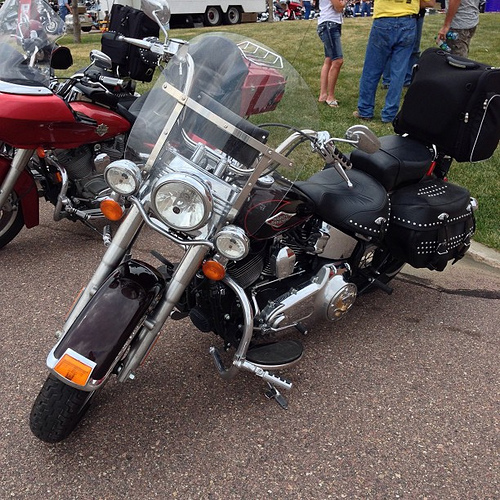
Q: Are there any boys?
A: No, there are no boys.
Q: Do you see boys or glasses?
A: No, there are no boys or glasses.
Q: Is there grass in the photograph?
A: Yes, there is grass.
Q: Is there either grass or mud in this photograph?
A: Yes, there is grass.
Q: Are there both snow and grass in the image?
A: No, there is grass but no snow.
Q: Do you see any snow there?
A: No, there is no snow.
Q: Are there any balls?
A: No, there are no balls.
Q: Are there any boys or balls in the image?
A: No, there are no balls or boys.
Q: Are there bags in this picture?
A: Yes, there is a bag.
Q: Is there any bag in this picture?
A: Yes, there is a bag.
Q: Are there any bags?
A: Yes, there is a bag.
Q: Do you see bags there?
A: Yes, there is a bag.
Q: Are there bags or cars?
A: Yes, there is a bag.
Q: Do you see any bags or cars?
A: Yes, there is a bag.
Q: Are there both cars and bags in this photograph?
A: No, there is a bag but no cars.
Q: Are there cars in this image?
A: No, there are no cars.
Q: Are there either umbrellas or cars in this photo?
A: No, there are no cars or umbrellas.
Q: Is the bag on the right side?
A: Yes, the bag is on the right of the image.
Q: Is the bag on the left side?
A: No, the bag is on the right of the image.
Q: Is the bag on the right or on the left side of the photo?
A: The bag is on the right of the image.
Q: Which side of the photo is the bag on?
A: The bag is on the right of the image.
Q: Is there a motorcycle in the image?
A: Yes, there is a motorcycle.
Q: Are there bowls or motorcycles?
A: Yes, there is a motorcycle.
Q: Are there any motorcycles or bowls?
A: Yes, there is a motorcycle.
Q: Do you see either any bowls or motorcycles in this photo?
A: Yes, there is a motorcycle.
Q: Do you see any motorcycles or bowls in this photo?
A: Yes, there is a motorcycle.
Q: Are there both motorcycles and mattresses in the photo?
A: No, there is a motorcycle but no mattresses.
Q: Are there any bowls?
A: No, there are no bowls.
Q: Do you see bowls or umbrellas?
A: No, there are no bowls or umbrellas.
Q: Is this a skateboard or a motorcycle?
A: This is a motorcycle.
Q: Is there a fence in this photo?
A: No, there are no fences.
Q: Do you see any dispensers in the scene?
A: No, there are no dispensers.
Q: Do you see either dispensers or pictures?
A: No, there are no dispensers or pictures.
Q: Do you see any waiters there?
A: No, there are no waiters.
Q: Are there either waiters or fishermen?
A: No, there are no waiters or fishermen.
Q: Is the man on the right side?
A: Yes, the man is on the right of the image.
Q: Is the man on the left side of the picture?
A: No, the man is on the right of the image.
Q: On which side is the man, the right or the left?
A: The man is on the right of the image.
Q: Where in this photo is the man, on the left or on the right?
A: The man is on the right of the image.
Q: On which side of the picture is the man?
A: The man is on the right of the image.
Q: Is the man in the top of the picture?
A: Yes, the man is in the top of the image.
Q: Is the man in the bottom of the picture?
A: No, the man is in the top of the image.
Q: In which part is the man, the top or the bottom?
A: The man is in the top of the image.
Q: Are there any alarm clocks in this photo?
A: No, there are no alarm clocks.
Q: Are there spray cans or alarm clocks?
A: No, there are no alarm clocks or spray cans.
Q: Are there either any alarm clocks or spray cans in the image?
A: No, there are no alarm clocks or spray cans.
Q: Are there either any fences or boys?
A: No, there are no boys or fences.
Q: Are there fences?
A: No, there are no fences.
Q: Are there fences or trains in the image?
A: No, there are no fences or trains.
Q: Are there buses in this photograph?
A: No, there are no buses.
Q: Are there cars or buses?
A: No, there are no buses or cars.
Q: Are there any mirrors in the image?
A: Yes, there is a mirror.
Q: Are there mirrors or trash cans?
A: Yes, there is a mirror.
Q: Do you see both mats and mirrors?
A: No, there is a mirror but no mats.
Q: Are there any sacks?
A: No, there are no sacks.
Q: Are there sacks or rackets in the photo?
A: No, there are no sacks or rackets.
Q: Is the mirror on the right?
A: Yes, the mirror is on the right of the image.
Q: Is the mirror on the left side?
A: No, the mirror is on the right of the image.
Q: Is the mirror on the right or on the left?
A: The mirror is on the right of the image.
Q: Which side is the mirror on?
A: The mirror is on the right of the image.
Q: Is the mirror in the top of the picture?
A: Yes, the mirror is in the top of the image.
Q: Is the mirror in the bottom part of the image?
A: No, the mirror is in the top of the image.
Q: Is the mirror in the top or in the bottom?
A: The mirror is in the top of the image.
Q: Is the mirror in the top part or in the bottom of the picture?
A: The mirror is in the top of the image.